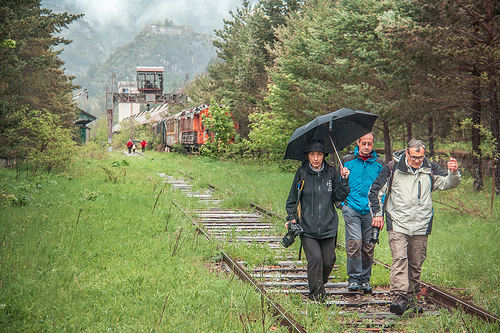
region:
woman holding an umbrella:
[281, 60, 378, 298]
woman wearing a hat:
[296, 134, 334, 161]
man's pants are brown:
[378, 223, 433, 308]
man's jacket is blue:
[341, 148, 386, 222]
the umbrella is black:
[282, 99, 384, 167]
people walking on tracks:
[282, 103, 467, 310]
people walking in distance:
[109, 128, 174, 161]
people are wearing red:
[116, 135, 153, 154]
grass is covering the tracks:
[143, 160, 496, 332]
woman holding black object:
[267, 208, 312, 255]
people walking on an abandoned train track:
[266, 105, 458, 316]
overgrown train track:
[141, 157, 279, 292]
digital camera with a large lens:
[272, 208, 312, 254]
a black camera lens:
[361, 206, 402, 258]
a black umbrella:
[268, 110, 405, 164]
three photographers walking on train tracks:
[257, 81, 490, 319]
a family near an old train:
[108, 124, 181, 169]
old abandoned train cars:
[151, 107, 253, 159]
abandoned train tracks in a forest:
[111, 132, 340, 329]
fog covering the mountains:
[57, 0, 252, 80]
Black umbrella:
[283, 107, 378, 158]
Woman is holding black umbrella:
[282, 105, 379, 303]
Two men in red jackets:
[126, 136, 146, 155]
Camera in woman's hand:
[280, 221, 302, 246]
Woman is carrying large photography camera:
[277, 140, 351, 310]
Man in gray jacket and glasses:
[370, 135, 462, 320]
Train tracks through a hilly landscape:
[115, 142, 497, 332]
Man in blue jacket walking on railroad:
[336, 129, 383, 294]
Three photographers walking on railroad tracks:
[277, 110, 455, 314]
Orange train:
[151, 103, 247, 153]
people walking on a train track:
[272, 102, 457, 313]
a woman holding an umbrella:
[272, 103, 378, 275]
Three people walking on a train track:
[272, 115, 464, 312]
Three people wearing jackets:
[284, 104, 474, 313]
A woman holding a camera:
[274, 216, 312, 253]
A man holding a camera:
[362, 151, 397, 246]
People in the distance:
[122, 130, 149, 156]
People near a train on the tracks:
[120, 131, 155, 161]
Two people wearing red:
[120, 130, 152, 152]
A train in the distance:
[148, 96, 245, 154]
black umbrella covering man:
[271, 100, 386, 180]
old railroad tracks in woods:
[108, 133, 493, 332]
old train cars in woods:
[103, 105, 238, 155]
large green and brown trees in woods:
[216, 4, 497, 169]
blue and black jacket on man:
[341, 151, 390, 216]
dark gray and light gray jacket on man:
[369, 154, 461, 244]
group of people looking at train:
[111, 135, 158, 156]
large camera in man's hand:
[272, 213, 305, 250]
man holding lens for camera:
[366, 218, 388, 247]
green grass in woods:
[7, 120, 248, 331]